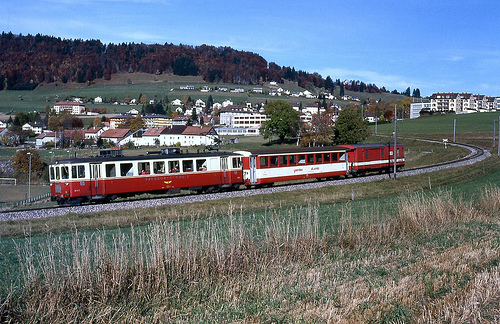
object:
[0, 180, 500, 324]
grass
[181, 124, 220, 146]
house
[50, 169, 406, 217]
gravel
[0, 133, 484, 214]
rails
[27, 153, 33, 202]
poles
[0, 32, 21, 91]
trees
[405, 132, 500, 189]
track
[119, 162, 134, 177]
windows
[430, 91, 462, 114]
buildings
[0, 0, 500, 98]
sky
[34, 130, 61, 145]
houses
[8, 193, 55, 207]
fence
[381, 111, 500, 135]
hill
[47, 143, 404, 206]
train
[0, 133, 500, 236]
railroad track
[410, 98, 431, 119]
building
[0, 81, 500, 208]
city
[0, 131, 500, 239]
track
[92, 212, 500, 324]
rockd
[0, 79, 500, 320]
field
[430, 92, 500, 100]
roof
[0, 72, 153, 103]
hills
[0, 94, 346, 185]
village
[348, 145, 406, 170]
stripe